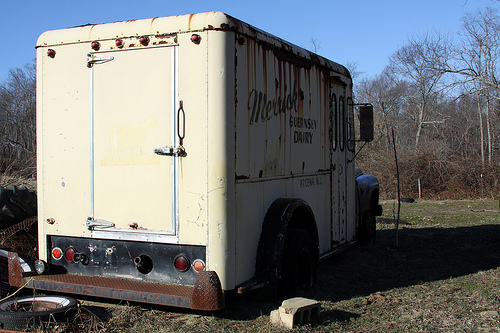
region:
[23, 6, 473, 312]
an old truck photo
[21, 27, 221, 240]
this truck has a backdoor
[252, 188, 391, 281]
the tires on this truck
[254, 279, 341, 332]
a brick by the truck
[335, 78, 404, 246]
the front end of the truck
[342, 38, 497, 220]
trees near the truck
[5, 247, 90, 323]
an old tire behind the truck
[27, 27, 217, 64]
lights at the top of the truck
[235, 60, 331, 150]
the truck company's name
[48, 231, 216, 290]
lights on the back of the truck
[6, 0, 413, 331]
an old milk truck is parked in a field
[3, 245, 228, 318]
the truck's bumper is rusted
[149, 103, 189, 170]
the rear door handle to the truck is rusting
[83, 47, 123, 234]
latches are on the truck rear door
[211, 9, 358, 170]
the roof is rusting down the side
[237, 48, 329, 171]
writing is visible on the side of the truck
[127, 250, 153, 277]
the truck's exhaust out the rear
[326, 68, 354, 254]
the side door of the truck has windows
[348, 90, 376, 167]
the truck's rear view mirror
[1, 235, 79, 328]
tires are laying on the ground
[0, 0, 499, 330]
A sunny day outside.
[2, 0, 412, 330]
An old rustry truck.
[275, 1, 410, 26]
The sky is blue.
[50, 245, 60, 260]
Tail light on the truck.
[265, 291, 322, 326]
A grey cinder block.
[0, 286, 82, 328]
A tire on the ground.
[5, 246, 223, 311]
The bumper on the truck is rusty.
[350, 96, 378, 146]
A mirror on the truck.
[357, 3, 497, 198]
Leaves on the trees.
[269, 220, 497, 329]
A shadow of the truck.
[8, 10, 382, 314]
A white and black dairy truck sitting.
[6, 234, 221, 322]
A rusty black bumper with three lights and two red reflectors.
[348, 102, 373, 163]
A truck mirror attached with brackets.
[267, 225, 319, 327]
Broken cement block in front of flat or buried tire.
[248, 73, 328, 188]
Faded lettering advertising a dairy.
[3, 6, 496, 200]
Trees in front of truck have no leaves.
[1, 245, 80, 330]
Two old tires laying on the ground.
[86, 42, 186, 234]
Door with one handle and two hinges.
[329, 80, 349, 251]
Door with two oval windows.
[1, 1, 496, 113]
Clear blue sky without any clouds.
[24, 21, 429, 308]
the truck is beige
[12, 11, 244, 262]
the truck is beige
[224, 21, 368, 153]
the truck is rusty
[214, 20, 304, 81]
the truck is rusty